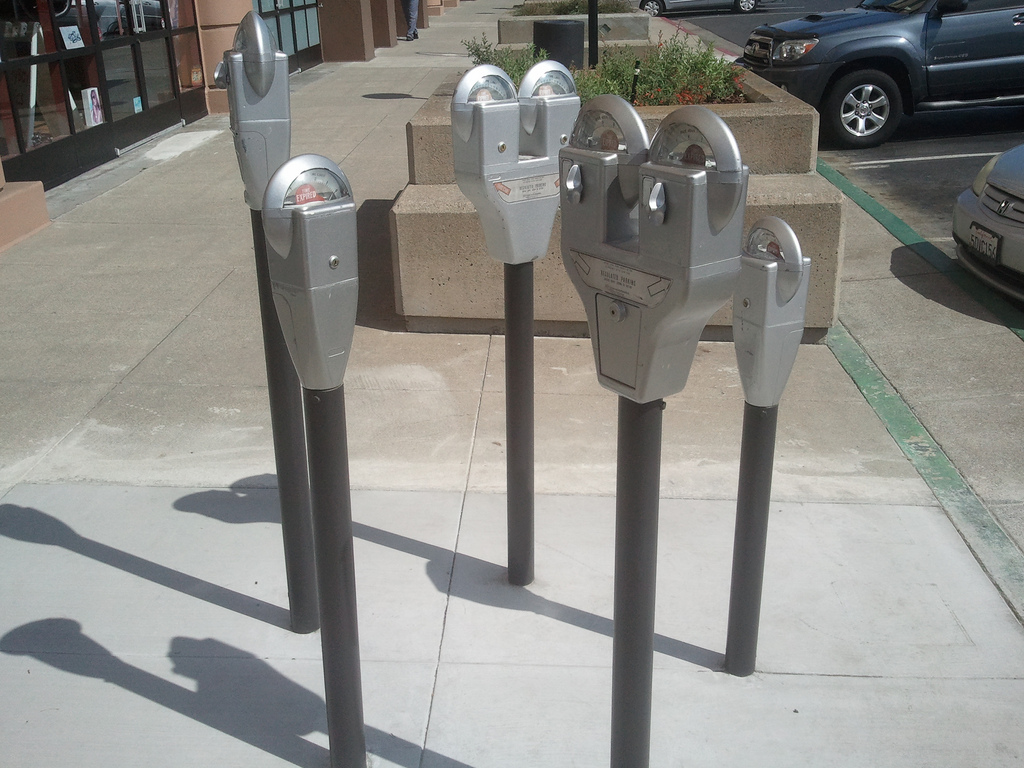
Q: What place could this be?
A: It is a sidewalk.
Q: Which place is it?
A: It is a sidewalk.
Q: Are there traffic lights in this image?
A: No, there are no traffic lights.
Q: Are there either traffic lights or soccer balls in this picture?
A: No, there are no traffic lights or soccer balls.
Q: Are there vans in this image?
A: No, there are no vans.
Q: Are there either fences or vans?
A: No, there are no vans or fences.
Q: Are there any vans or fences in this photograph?
A: No, there are no vans or fences.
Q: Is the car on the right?
A: Yes, the car is on the right of the image.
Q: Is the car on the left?
A: No, the car is on the right of the image.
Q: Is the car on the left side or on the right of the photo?
A: The car is on the right of the image.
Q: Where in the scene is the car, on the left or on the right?
A: The car is on the right of the image.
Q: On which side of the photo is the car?
A: The car is on the right of the image.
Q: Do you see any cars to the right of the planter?
A: Yes, there is a car to the right of the planter.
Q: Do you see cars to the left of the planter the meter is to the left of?
A: No, the car is to the right of the planter.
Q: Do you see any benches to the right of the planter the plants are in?
A: No, there is a car to the right of the planter.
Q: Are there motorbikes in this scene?
A: No, there are no motorbikes.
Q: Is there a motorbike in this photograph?
A: No, there are no motorcycles.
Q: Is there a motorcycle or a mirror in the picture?
A: No, there are no motorcycles or mirrors.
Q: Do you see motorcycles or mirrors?
A: No, there are no motorcycles or mirrors.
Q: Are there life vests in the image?
A: No, there are no life vests.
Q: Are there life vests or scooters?
A: No, there are no life vests or scooters.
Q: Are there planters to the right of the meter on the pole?
A: Yes, there is a planter to the right of the parking meter.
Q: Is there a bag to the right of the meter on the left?
A: No, there is a planter to the right of the parking meter.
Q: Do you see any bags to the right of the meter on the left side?
A: No, there is a planter to the right of the parking meter.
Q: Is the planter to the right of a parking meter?
A: Yes, the planter is to the right of a parking meter.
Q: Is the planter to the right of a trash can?
A: No, the planter is to the right of a parking meter.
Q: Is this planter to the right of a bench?
A: No, the planter is to the right of a parking meter.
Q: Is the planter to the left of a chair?
A: No, the planter is to the left of a car.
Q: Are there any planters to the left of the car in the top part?
A: Yes, there is a planter to the left of the car.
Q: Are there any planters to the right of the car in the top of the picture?
A: No, the planter is to the left of the car.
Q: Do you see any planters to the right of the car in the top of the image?
A: No, the planter is to the left of the car.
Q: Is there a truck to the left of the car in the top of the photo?
A: No, there is a planter to the left of the car.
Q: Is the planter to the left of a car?
A: Yes, the planter is to the left of a car.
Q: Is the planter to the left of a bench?
A: No, the planter is to the left of a car.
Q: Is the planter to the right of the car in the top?
A: No, the planter is to the left of the car.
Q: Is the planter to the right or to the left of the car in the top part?
A: The planter is to the left of the car.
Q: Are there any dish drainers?
A: No, there are no dish drainers.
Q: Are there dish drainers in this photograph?
A: No, there are no dish drainers.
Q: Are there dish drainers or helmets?
A: No, there are no dish drainers or helmets.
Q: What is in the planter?
A: The plants are in the planter.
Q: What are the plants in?
A: The plants are in the planter.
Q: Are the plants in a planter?
A: Yes, the plants are in a planter.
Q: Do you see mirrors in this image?
A: No, there are no mirrors.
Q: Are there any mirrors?
A: No, there are no mirrors.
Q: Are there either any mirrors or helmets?
A: No, there are no mirrors or helmets.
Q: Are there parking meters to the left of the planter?
A: Yes, there is a parking meter to the left of the planter.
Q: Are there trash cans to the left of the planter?
A: No, there is a parking meter to the left of the planter.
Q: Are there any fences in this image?
A: No, there are no fences.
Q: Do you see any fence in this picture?
A: No, there are no fences.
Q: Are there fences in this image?
A: No, there are no fences.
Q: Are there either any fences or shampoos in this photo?
A: No, there are no fences or shampoos.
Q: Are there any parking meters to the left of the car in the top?
A: Yes, there is a parking meter to the left of the car.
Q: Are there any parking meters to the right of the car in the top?
A: No, the parking meter is to the left of the car.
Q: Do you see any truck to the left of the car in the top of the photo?
A: No, there is a parking meter to the left of the car.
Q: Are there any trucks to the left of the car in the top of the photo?
A: No, there is a parking meter to the left of the car.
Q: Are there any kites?
A: No, there are no kites.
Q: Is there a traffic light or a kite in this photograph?
A: No, there are no kites or traffic lights.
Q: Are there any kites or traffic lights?
A: No, there are no kites or traffic lights.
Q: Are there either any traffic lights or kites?
A: No, there are no kites or traffic lights.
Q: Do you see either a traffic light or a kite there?
A: No, there are no kites or traffic lights.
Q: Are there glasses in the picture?
A: No, there are no glasses.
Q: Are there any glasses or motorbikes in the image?
A: No, there are no glasses or motorbikes.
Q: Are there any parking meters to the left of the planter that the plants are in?
A: Yes, there is a parking meter to the left of the planter.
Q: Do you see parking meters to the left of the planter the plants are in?
A: Yes, there is a parking meter to the left of the planter.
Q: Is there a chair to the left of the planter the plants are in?
A: No, there is a parking meter to the left of the planter.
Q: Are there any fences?
A: No, there are no fences.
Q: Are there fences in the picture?
A: No, there are no fences.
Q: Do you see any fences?
A: No, there are no fences.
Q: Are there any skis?
A: No, there are no skis.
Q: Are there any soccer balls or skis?
A: No, there are no skis or soccer balls.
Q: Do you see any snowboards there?
A: No, there are no snowboards.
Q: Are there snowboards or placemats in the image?
A: No, there are no snowboards or placemats.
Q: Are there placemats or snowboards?
A: No, there are no snowboards or placemats.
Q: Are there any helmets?
A: No, there are no helmets.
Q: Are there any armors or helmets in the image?
A: No, there are no helmets or armors.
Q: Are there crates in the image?
A: No, there are no crates.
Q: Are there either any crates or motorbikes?
A: No, there are no crates or motorbikes.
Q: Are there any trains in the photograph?
A: No, there are no trains.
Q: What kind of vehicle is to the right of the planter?
A: The vehicle is a car.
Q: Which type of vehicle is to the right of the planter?
A: The vehicle is a car.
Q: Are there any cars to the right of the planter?
A: Yes, there is a car to the right of the planter.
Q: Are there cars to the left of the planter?
A: No, the car is to the right of the planter.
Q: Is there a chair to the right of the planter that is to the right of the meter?
A: No, there is a car to the right of the planter.